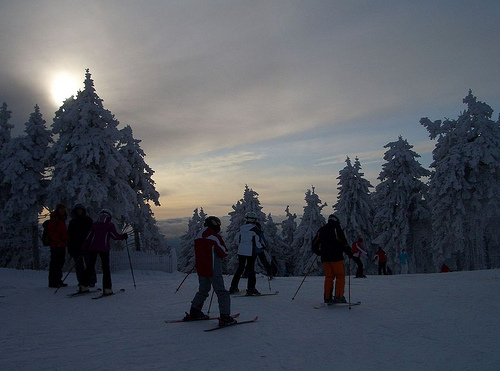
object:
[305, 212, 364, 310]
person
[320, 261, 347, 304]
red pants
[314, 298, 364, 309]
two skis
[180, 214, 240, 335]
person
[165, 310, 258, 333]
two skis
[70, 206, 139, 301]
person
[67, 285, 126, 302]
two skis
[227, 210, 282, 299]
person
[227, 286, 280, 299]
two skis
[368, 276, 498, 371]
snow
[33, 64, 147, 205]
snow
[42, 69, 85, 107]
sun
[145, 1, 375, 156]
sky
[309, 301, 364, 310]
skis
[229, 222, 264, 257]
white coat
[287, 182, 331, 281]
trees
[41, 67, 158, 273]
tree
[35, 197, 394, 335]
people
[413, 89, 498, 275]
tree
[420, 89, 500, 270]
snow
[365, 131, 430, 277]
tree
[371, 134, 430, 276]
snow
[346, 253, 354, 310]
ski pole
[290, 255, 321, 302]
ski pole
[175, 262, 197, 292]
ski pole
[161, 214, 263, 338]
skier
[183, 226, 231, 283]
red jacket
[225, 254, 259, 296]
black pants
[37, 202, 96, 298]
two people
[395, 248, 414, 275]
person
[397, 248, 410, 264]
blue jacket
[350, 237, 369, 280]
person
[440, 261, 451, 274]
torso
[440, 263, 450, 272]
skiier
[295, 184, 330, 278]
tree